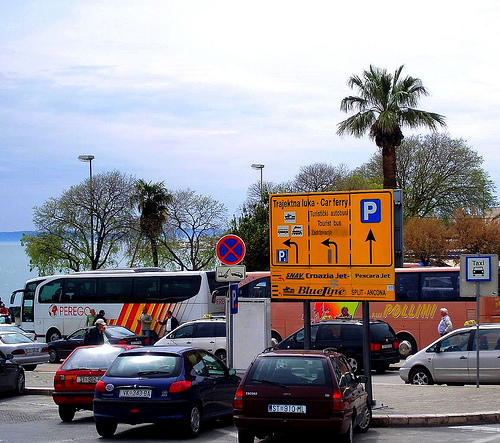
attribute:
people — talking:
[67, 303, 186, 362]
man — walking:
[77, 300, 118, 379]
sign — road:
[246, 167, 427, 325]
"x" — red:
[201, 223, 253, 296]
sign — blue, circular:
[188, 220, 258, 270]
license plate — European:
[259, 392, 328, 427]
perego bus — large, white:
[3, 248, 218, 368]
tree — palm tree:
[129, 161, 184, 272]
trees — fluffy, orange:
[385, 190, 498, 304]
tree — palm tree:
[319, 46, 460, 236]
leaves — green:
[329, 66, 455, 145]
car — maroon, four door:
[221, 330, 402, 441]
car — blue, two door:
[86, 324, 251, 441]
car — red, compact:
[48, 330, 138, 427]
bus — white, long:
[0, 256, 250, 366]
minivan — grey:
[400, 308, 496, 400]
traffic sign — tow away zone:
[190, 200, 267, 320]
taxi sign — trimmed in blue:
[431, 232, 498, 300]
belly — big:
[429, 270, 460, 369]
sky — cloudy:
[29, 0, 496, 160]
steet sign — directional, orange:
[229, 180, 428, 311]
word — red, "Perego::
[41, 294, 117, 324]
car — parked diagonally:
[228, 329, 371, 440]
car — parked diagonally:
[94, 329, 243, 440]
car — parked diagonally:
[39, 325, 140, 430]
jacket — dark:
[159, 315, 179, 330]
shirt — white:
[162, 315, 174, 335]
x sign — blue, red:
[214, 229, 247, 272]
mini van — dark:
[254, 306, 414, 383]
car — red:
[224, 338, 416, 441]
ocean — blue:
[0, 219, 255, 321]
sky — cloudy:
[0, 1, 498, 228]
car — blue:
[91, 342, 257, 440]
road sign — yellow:
[259, 183, 402, 314]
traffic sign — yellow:
[268, 189, 400, 305]